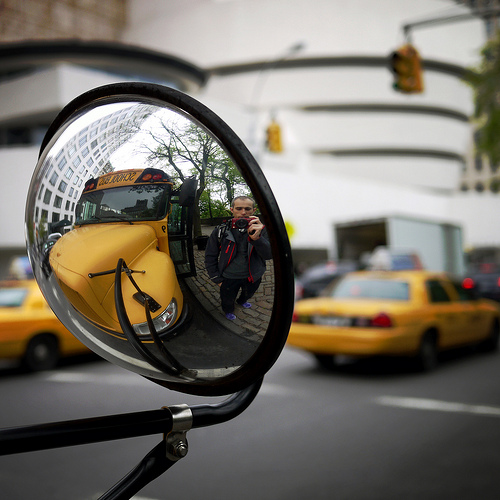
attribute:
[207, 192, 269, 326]
man — reflected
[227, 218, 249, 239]
camera — reflected, red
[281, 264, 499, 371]
taxi — yellow, here, braking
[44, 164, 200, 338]
bus — yellow, school, reflected, large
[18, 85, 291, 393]
mirror — here, round, large, silver, black, metal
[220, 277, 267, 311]
pants — black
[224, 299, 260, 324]
sneakers — blue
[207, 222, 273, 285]
jacket — black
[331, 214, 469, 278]
truck — white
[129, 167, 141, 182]
letter — s, backwards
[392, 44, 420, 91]
light — yellow, overhead, traffic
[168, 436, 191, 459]
bolt — metal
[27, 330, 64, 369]
tire — black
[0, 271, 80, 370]
cab — yellow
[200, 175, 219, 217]
leaves — green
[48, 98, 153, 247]
building — reflected, tall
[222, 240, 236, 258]
trim — red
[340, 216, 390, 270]
door — open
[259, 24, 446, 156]
lights — traffic, yellow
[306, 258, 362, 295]
van — midsized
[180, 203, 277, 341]
sidewalk — bricked, red